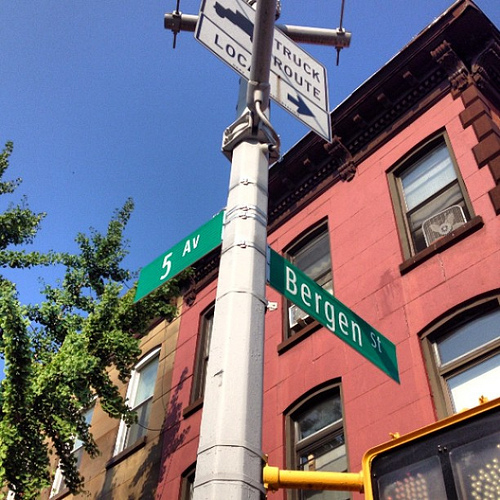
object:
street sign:
[132, 209, 224, 304]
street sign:
[265, 241, 400, 386]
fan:
[421, 204, 468, 247]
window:
[392, 134, 472, 256]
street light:
[262, 394, 500, 499]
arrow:
[287, 92, 318, 118]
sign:
[192, 0, 337, 144]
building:
[154, 0, 500, 500]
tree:
[0, 139, 198, 500]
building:
[0, 274, 184, 500]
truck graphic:
[211, 0, 256, 43]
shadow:
[93, 364, 191, 499]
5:
[159, 251, 174, 281]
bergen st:
[285, 265, 384, 356]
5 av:
[159, 233, 201, 281]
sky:
[0, 0, 500, 380]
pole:
[189, 0, 281, 498]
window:
[280, 218, 336, 343]